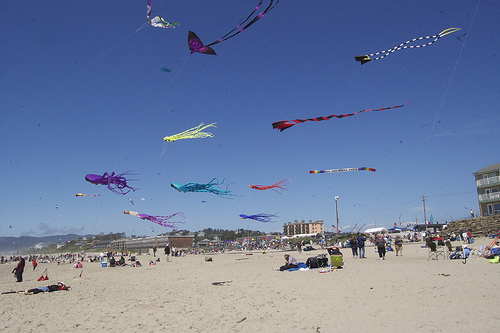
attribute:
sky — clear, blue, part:
[6, 5, 120, 120]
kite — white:
[354, 52, 372, 66]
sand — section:
[1, 251, 500, 333]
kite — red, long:
[273, 100, 406, 132]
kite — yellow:
[163, 122, 219, 143]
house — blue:
[472, 160, 500, 218]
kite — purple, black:
[241, 212, 279, 224]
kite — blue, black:
[170, 178, 245, 203]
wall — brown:
[442, 215, 500, 236]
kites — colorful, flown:
[77, 173, 292, 229]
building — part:
[283, 217, 324, 237]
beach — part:
[2, 240, 499, 332]